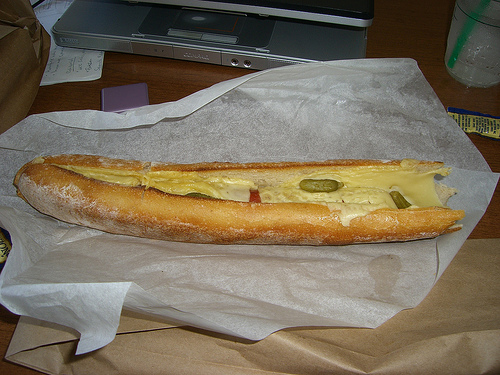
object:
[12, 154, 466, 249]
baguette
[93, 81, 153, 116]
piece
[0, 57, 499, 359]
wax paper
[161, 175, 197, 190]
cheese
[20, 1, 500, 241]
table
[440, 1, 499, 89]
beverage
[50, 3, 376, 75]
laptop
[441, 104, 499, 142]
packet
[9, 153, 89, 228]
end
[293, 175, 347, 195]
jalapeno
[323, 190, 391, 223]
egg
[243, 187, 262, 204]
bell pepper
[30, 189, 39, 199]
flour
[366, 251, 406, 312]
stain